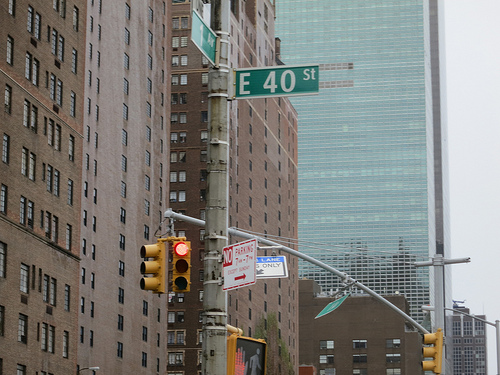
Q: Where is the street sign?
A: Metal pole.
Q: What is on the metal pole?
A: Street sign.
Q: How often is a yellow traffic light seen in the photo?
A: Three times.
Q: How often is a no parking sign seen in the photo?
A: One time.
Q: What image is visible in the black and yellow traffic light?
A: Human figure and human hand.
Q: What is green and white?
A: The street sign.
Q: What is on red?
A: The street light.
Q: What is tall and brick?
A: The building.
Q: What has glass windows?
A: The skyscraper.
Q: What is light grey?
A: The streetlight pole.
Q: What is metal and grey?
A: The pole.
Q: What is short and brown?
A: The building.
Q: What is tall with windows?
A: The glass building.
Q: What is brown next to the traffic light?
A: The building.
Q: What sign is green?
A: Street sign.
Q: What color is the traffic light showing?
A: Red.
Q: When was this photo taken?
A: During the daytime.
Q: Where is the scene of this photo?
A: In a city.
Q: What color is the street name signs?
A: Green.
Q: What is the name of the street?
A: E 40th Street.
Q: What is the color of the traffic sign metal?
A: Yellow.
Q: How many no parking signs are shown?
A: One.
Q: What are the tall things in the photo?
A: Buildings.